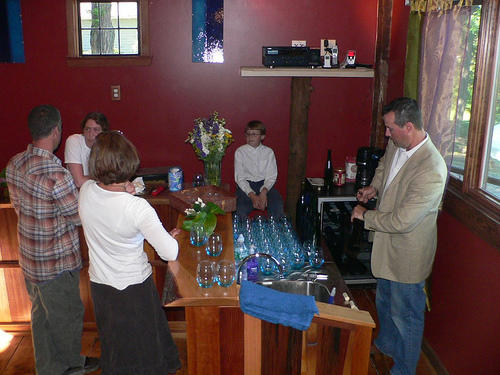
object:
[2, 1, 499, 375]
room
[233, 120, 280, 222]
boy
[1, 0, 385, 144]
wall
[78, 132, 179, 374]
woman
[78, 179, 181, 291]
shirt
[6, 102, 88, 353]
man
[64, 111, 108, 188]
woman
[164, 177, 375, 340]
bar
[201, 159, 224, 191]
vase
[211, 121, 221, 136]
flowers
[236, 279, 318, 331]
cloth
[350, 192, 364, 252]
bottle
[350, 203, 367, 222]
hand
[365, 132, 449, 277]
suit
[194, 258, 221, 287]
glasses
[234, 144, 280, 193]
shirt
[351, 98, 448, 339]
man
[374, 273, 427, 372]
pants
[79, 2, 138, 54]
window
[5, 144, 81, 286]
shirt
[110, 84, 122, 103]
outlet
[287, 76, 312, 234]
pole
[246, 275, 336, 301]
sink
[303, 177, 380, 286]
fridge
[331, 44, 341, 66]
phone